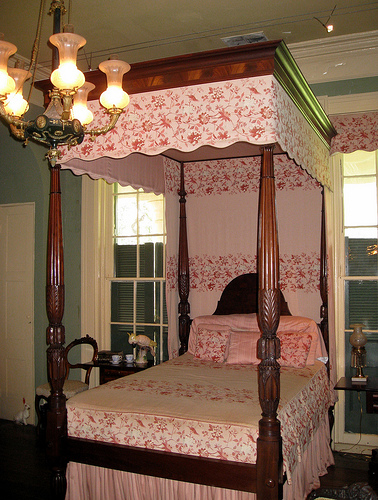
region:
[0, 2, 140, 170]
a chandelier light hanging from a ceiling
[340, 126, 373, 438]
a window in a room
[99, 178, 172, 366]
a window in a room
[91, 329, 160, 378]
a bed side with things on the top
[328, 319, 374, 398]
a lamp on a bed side table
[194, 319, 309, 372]
some pillows on a bed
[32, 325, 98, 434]
a chair in a corner by a window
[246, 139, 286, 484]
a post of a four post bed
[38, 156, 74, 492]
a post of a four post bed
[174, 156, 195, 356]
a post of a four post bed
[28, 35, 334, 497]
A wooden four post bed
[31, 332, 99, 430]
A wooden chair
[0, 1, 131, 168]
A light fixture hanging from the ceiling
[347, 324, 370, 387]
A bedside table lamp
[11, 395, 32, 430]
A bunny shaped door stop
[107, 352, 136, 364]
Two tea cups in saucers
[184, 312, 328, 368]
Pink and flowered designed pillows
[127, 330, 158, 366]
A ceramic knick knack on a table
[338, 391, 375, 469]
The electrical plug of the lamp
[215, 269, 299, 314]
The wooden headboard of the bed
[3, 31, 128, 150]
ornate ceiling light fixture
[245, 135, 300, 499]
carved wooden bed post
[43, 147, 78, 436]
carved wooden fence post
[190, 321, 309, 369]
pillows on a bed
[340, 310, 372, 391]
unlit lamp by the bed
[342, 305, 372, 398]
lamp on a night stand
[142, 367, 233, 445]
pink bed spread on a bed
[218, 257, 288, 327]
ornage wooden head board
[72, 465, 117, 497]
pink dust cover on a bed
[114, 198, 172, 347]
white window panes on a window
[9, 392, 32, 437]
an old rabbit door stop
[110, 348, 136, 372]
two tea cups sitting on the night stand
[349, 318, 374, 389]
an old hurricane lamp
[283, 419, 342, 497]
a pink bed skirt with ruffles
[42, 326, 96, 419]
old fashioned looking chair with white padded seat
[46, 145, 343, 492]
an old four poster bed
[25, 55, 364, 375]
four poster bed with canopy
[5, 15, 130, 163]
an old fashioned chandelier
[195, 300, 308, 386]
decorative throw pillows on bed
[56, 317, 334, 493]
bed spread set that is pink with darker pink flowers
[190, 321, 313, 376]
Three pink and red pillows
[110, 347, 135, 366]
Two white cups on side table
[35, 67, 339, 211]
Pink and red canopy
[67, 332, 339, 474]
Pink and red sheets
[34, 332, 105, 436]
White and brown decoration table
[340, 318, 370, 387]
Small old style lamp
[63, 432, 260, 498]
Small piece of brown footboard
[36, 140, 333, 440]
Four brown canopy posts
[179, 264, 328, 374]
Pretty brown headboard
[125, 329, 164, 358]
Small glass white cockatoo